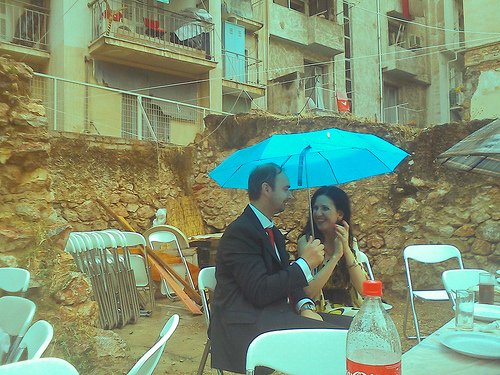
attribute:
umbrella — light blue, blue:
[208, 128, 410, 274]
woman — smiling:
[295, 182, 367, 316]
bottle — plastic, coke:
[343, 275, 403, 374]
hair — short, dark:
[247, 161, 283, 204]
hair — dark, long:
[300, 184, 351, 285]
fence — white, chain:
[25, 69, 236, 146]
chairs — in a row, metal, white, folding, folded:
[65, 228, 197, 328]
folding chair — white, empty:
[400, 243, 465, 343]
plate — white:
[436, 329, 499, 361]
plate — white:
[453, 301, 498, 321]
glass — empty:
[453, 288, 477, 332]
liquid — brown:
[477, 281, 494, 305]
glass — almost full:
[477, 268, 496, 304]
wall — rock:
[1, 54, 499, 297]